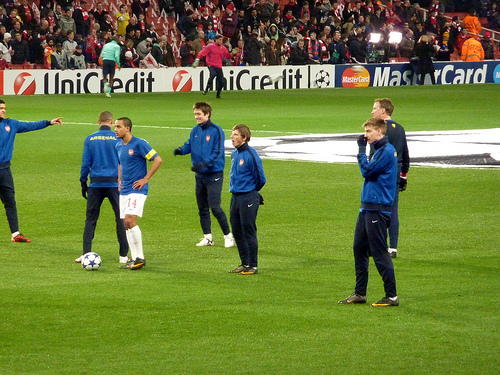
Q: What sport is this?
A: Soccer.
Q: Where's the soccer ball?
A: Left.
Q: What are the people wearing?
A: Windbreakers.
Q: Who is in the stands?
A: Fans.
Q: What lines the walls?
A: Ads.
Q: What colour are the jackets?
A: Blue.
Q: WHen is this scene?
A: Afternoon.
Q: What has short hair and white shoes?
A: The soccer player.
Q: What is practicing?
A: Two soccer players.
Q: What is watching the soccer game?
A: The crowd.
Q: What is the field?
A: Green.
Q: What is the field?
A: Green.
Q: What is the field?
A: Green.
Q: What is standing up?
A: The people.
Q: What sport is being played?
A: Soccer.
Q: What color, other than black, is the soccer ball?
A: White.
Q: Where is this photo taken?
A: A soccer field.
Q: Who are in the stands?
A: Fans.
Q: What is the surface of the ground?
A: Turf.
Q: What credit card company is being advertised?
A: Master Card.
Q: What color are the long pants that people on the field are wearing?
A: Black.